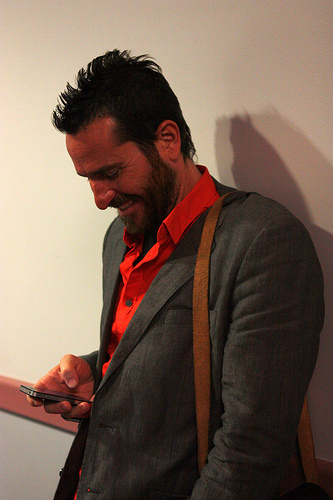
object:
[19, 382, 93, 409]
mobile phone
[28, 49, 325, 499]
man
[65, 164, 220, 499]
shirt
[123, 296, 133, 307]
button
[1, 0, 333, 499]
wall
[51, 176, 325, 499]
blazer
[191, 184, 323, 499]
bag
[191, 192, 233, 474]
strap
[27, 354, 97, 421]
right hand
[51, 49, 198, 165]
hair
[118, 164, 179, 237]
beard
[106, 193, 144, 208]
mustache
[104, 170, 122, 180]
eye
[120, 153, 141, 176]
crow's feet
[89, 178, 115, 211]
nose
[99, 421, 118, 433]
button hole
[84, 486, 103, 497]
button hole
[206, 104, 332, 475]
shadow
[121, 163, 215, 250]
collar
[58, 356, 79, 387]
thumb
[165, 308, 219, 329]
pocket